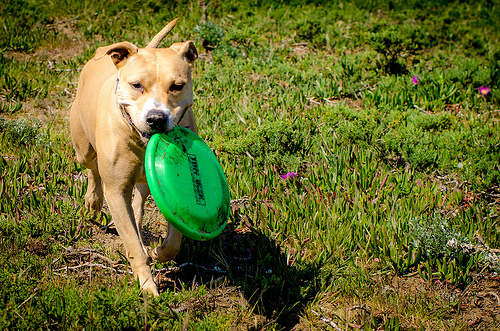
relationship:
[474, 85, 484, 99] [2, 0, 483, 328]
flower in field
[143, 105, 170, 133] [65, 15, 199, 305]
nose of dog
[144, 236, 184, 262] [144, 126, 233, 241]
paw nearest frisbee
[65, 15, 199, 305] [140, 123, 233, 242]
dog and h toy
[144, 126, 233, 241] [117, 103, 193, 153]
frisbee in mouth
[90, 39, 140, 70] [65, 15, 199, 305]
ear on dog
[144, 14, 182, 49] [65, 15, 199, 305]
tail of dog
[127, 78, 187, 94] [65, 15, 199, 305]
eyes on dog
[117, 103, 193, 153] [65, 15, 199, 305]
mouth of dog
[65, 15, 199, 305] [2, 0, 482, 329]
dog walking in grass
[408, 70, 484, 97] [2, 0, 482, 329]
flowers in grass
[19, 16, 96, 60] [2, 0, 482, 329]
patch in grass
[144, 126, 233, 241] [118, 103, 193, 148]
frisbee in mouth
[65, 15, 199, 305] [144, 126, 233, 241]
dog holding frisbee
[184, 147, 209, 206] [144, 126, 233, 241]
writing on frisbee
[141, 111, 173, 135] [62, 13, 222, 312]
nose on dog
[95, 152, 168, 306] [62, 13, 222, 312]
legs on dog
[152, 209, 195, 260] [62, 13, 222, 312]
legs on dog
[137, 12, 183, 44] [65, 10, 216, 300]
tail on dog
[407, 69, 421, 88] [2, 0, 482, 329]
flower in grass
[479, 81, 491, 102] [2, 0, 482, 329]
flower in grass